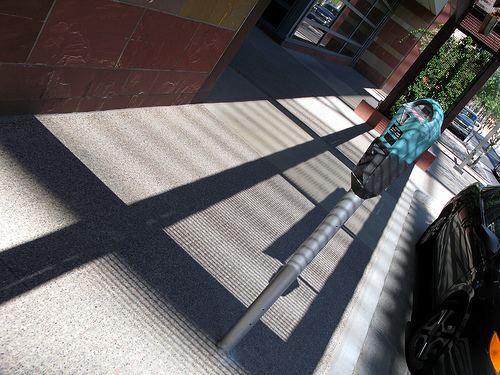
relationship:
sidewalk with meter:
[155, 122, 246, 240] [359, 74, 426, 213]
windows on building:
[301, 14, 349, 49] [177, 15, 272, 78]